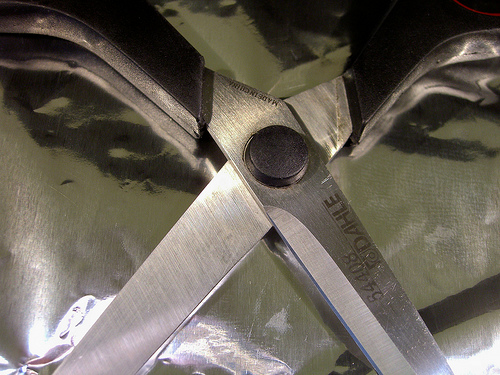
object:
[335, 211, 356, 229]
letter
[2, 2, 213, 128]
handle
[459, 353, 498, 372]
light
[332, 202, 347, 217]
letter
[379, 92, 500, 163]
reflection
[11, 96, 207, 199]
reflection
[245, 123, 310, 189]
connector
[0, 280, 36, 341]
foil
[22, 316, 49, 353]
light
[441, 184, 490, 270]
tin foil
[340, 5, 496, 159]
handle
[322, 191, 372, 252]
dahle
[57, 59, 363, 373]
blade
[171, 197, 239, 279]
silver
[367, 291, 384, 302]
number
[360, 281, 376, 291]
number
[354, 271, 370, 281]
number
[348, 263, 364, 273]
number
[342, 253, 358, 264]
number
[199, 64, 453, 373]
blade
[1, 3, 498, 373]
scissor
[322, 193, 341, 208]
letter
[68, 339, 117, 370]
metal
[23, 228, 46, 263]
aluminum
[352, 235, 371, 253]
letter d